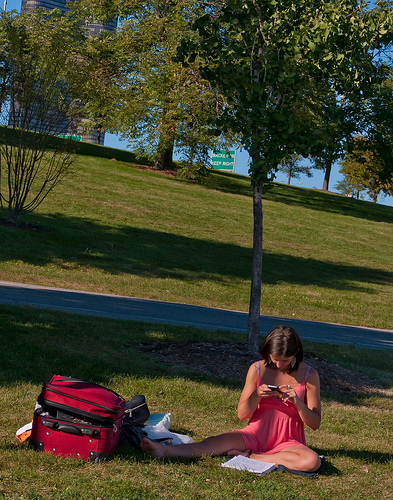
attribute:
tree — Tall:
[200, 6, 383, 338]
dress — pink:
[240, 358, 314, 446]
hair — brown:
[253, 316, 306, 369]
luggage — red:
[23, 366, 131, 472]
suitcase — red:
[51, 371, 129, 447]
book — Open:
[220, 453, 275, 476]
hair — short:
[262, 322, 304, 372]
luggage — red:
[17, 362, 155, 449]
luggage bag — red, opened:
[12, 374, 129, 470]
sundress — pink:
[230, 358, 310, 455]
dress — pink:
[212, 330, 325, 479]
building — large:
[8, 0, 120, 147]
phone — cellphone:
[267, 381, 278, 391]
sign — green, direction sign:
[209, 146, 238, 172]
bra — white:
[246, 359, 313, 394]